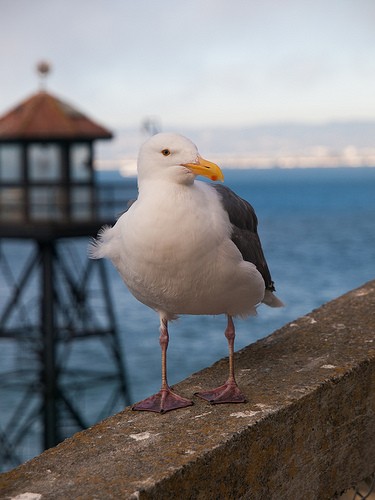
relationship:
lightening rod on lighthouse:
[37, 61, 49, 89] [0, 61, 137, 470]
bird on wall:
[83, 132, 278, 415] [5, 340, 371, 493]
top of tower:
[2, 60, 113, 139] [2, 57, 135, 484]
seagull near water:
[87, 131, 284, 415] [248, 167, 363, 257]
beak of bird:
[183, 158, 223, 182] [83, 132, 278, 415]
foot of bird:
[125, 382, 197, 417] [83, 132, 278, 415]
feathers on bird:
[214, 182, 278, 295] [83, 132, 278, 415]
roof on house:
[3, 86, 93, 142] [1, 90, 114, 228]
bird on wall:
[83, 132, 278, 415] [3, 278, 373, 499]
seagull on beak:
[87, 131, 284, 415] [183, 158, 223, 182]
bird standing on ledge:
[105, 132, 277, 414] [1, 279, 373, 498]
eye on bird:
[158, 147, 171, 155] [83, 132, 278, 415]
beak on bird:
[181, 156, 224, 182] [83, 132, 278, 415]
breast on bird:
[146, 219, 221, 300] [83, 132, 278, 415]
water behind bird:
[2, 164, 373, 470] [105, 132, 277, 414]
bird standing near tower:
[14, 47, 290, 443] [2, 57, 135, 484]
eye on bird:
[158, 147, 171, 155] [37, 113, 328, 415]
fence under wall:
[335, 480, 373, 498] [253, 284, 374, 485]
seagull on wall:
[87, 131, 284, 415] [262, 378, 332, 472]